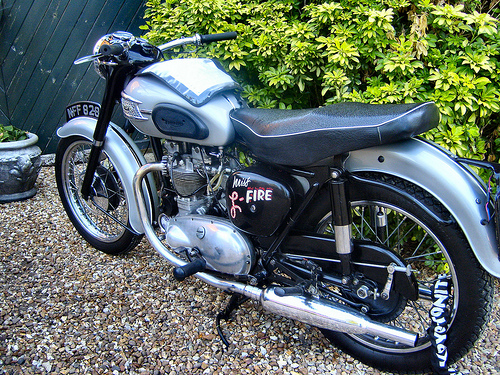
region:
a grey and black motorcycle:
[53, 28, 488, 365]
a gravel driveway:
[2, 162, 498, 374]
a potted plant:
[5, 115, 58, 202]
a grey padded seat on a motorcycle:
[231, 85, 432, 156]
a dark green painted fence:
[6, 3, 158, 158]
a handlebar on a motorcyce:
[169, 21, 252, 59]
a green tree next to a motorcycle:
[145, 4, 499, 186]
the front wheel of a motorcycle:
[42, 116, 155, 268]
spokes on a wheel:
[308, 208, 450, 349]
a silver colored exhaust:
[222, 276, 424, 350]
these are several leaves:
[441, 79, 498, 138]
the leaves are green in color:
[448, 81, 477, 138]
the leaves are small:
[447, 82, 484, 128]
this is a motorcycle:
[239, 110, 434, 132]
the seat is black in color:
[257, 112, 342, 127]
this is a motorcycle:
[49, 27, 496, 366]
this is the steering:
[73, 19, 240, 80]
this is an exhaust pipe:
[296, 301, 431, 351]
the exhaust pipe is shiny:
[300, 301, 348, 325]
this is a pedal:
[170, 242, 201, 282]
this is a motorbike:
[67, 30, 477, 360]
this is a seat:
[242, 93, 377, 150]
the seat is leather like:
[239, 87, 360, 159]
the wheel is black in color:
[403, 226, 463, 373]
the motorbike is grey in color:
[120, 87, 165, 130]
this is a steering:
[157, 22, 243, 55]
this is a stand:
[210, 297, 246, 341]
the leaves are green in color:
[284, 11, 364, 86]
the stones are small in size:
[42, 260, 148, 372]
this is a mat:
[152, 62, 215, 96]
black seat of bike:
[265, 70, 430, 156]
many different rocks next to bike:
[35, 275, 146, 351]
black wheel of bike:
[422, 255, 492, 331]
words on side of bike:
[201, 166, 271, 236]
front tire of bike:
[55, 131, 122, 231]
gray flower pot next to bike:
[0, 110, 46, 185]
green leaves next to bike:
[295, 10, 400, 75]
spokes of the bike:
[396, 231, 431, 281]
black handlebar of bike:
[186, 20, 246, 65]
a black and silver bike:
[51, 25, 467, 296]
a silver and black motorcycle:
[52, 12, 494, 360]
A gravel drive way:
[3, 241, 126, 336]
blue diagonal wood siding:
[4, 4, 76, 88]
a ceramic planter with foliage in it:
[0, 122, 46, 206]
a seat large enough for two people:
[209, 72, 449, 177]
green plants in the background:
[255, 0, 476, 95]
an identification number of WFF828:
[43, 94, 119, 131]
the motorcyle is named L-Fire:
[210, 161, 302, 258]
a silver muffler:
[206, 263, 423, 361]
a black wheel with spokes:
[52, 117, 145, 256]